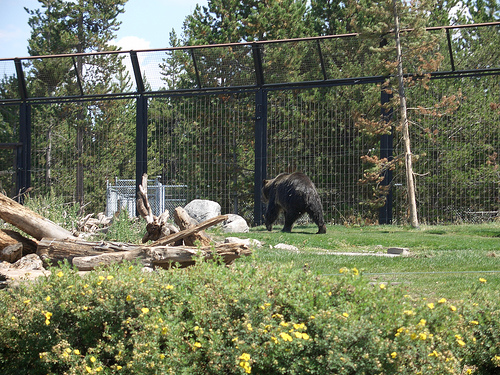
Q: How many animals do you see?
A: One.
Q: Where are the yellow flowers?
A: In the front of the photo.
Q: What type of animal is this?
A: A bear.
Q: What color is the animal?
A: Black.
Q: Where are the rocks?
A: In the center.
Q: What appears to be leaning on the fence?
A: A small tree.